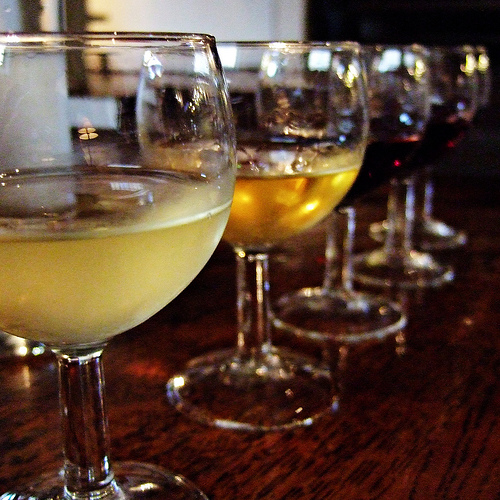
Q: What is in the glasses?
A: Wine.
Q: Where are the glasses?
A: A table.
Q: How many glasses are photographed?
A: Five.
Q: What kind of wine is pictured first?
A: White.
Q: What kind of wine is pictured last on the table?
A: Red.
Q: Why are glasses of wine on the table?
A: To drink.